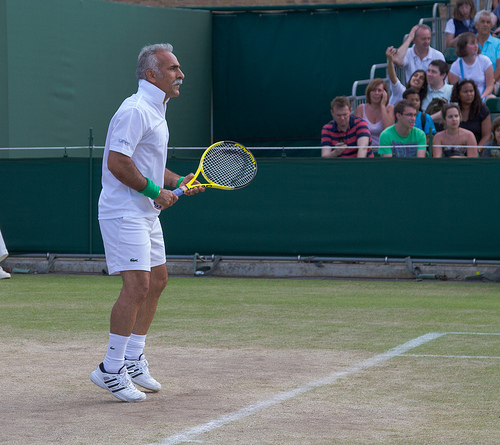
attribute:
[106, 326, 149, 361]
white socks — long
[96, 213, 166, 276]
sport shorts — white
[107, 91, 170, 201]
shirt — white, short sleeved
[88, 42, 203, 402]
man — older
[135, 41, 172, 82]
hair — grey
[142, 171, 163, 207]
arm band — green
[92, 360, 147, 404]
shoes — white, black, tennis shoes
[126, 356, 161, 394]
shoes — white, black, tennis shoes